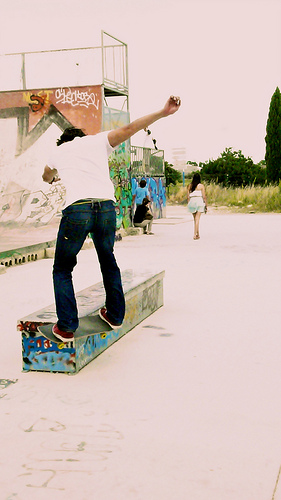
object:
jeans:
[52, 200, 125, 332]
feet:
[193, 233, 200, 240]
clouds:
[134, 26, 239, 86]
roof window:
[148, 39, 258, 85]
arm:
[108, 93, 181, 147]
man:
[133, 198, 155, 236]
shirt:
[133, 206, 149, 223]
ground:
[0, 264, 280, 498]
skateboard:
[37, 314, 114, 342]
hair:
[189, 173, 201, 193]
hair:
[56, 126, 86, 146]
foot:
[99, 306, 123, 328]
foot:
[52, 321, 75, 343]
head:
[192, 173, 200, 183]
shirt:
[189, 189, 202, 196]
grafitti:
[108, 149, 166, 229]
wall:
[0, 85, 129, 220]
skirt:
[187, 196, 205, 213]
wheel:
[57, 343, 63, 350]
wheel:
[100, 332, 106, 338]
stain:
[142, 325, 163, 329]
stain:
[160, 332, 170, 336]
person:
[41, 95, 180, 343]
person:
[188, 172, 207, 239]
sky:
[0, 0, 281, 87]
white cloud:
[144, 33, 166, 51]